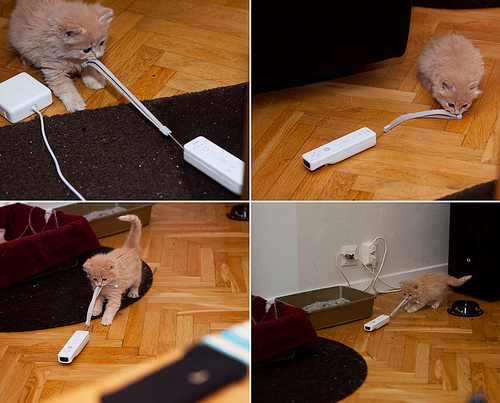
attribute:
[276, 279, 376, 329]
tray — brown, plastic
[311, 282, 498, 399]
floor — wooden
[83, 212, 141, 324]
kitten — tan, playing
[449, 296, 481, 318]
bowl — silver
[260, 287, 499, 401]
floor — wooden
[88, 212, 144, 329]
kitten — playing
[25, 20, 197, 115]
kitty — orange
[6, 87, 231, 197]
rug — black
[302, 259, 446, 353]
box — brown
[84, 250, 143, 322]
kitten — orange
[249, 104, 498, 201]
floor — wood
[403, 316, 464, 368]
floor — wood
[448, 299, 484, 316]
pet bowl — silver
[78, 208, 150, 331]
kitten — tan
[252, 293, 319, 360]
box — red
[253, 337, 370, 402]
carpet — black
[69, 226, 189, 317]
cat — sitting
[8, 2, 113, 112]
kitten — tan, pulling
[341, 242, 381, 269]
board — electric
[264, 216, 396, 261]
wall — white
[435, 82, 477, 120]
face — orange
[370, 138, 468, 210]
floor — wooden